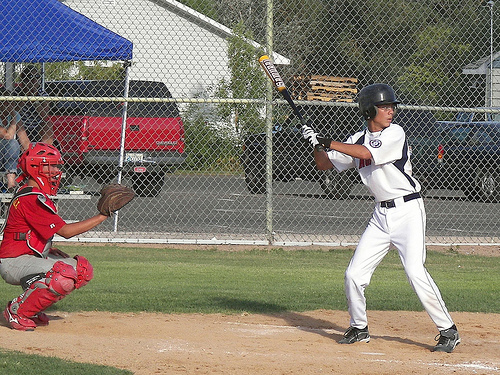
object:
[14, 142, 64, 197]
helmet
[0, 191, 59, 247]
chest gear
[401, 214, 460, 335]
leg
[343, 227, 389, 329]
leg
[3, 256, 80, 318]
leg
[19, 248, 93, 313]
leg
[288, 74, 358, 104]
pallets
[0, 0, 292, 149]
house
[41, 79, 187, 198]
suv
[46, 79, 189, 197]
red truck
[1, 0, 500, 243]
fence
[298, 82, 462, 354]
baseball player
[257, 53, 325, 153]
bat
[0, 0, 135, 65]
tent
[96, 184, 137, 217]
baseball glove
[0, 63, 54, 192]
people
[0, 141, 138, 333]
catcher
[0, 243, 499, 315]
green grass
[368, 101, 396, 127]
head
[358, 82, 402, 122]
helmet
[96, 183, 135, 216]
hand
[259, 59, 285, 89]
letters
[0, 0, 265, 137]
background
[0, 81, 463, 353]
baseball